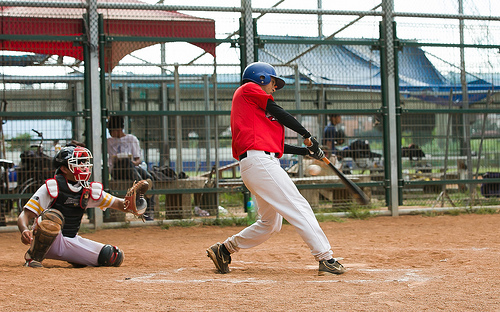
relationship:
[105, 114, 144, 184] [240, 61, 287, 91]
fan wearing baseball helmet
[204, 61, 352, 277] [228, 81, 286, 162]
baseball player with a jersey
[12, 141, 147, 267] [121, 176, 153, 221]
boy with glove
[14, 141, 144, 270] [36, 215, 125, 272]
boy with knee pads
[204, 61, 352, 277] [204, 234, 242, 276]
baseball player with a shoe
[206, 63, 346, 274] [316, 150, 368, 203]
baseball player swinging a bat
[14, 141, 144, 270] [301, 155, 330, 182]
boy crouching to receive ball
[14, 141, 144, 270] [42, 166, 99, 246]
boy with a chestguard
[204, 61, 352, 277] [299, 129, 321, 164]
baseball player has gloves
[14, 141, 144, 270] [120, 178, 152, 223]
boy has glove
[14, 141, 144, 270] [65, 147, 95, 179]
boy has mask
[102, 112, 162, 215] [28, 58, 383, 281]
fan at a game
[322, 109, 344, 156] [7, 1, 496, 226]
man walking behind fence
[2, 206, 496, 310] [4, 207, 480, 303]
dirt on field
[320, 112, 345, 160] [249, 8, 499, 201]
man in dugout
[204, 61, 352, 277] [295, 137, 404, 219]
baseball player swings bat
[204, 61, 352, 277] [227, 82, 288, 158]
baseball player wearing jersey